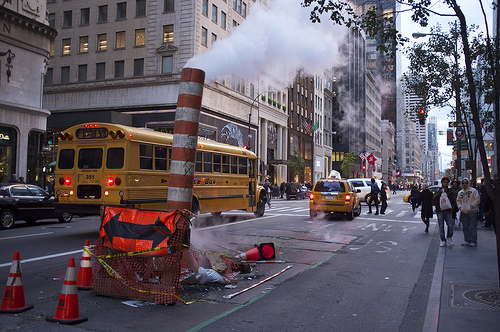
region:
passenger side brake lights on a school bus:
[105, 176, 115, 186]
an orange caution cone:
[47, 255, 89, 322]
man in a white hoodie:
[455, 177, 481, 245]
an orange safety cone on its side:
[232, 242, 276, 259]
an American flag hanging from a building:
[301, 116, 313, 133]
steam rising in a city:
[249, 8, 331, 69]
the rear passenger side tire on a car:
[1, 213, 13, 228]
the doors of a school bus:
[247, 155, 257, 210]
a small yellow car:
[309, 169, 361, 219]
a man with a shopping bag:
[436, 177, 454, 245]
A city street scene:
[8, 5, 498, 321]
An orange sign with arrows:
[86, 192, 182, 259]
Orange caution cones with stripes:
[1, 236, 99, 326]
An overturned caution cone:
[229, 235, 281, 265]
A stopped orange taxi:
[308, 169, 361, 218]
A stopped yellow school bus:
[56, 109, 284, 220]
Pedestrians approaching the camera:
[432, 177, 489, 322]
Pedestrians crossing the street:
[368, 167, 414, 220]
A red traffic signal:
[413, 106, 429, 126]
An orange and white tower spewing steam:
[163, 55, 210, 212]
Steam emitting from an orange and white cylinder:
[169, 2, 387, 121]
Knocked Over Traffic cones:
[203, 234, 306, 279]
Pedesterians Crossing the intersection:
[363, 174, 408, 231]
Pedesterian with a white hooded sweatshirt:
[454, 175, 486, 260]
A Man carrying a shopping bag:
[430, 175, 458, 254]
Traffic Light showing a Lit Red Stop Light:
[404, 101, 456, 128]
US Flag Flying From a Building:
[286, 116, 321, 141]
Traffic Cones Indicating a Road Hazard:
[3, 207, 310, 327]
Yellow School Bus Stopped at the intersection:
[47, 121, 326, 231]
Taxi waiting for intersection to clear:
[288, 167, 401, 227]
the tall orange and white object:
[165, 65, 205, 278]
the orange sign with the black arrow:
[98, 203, 178, 255]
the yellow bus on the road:
[53, 120, 267, 217]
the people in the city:
[0, 160, 499, 253]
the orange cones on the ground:
[1, 238, 276, 323]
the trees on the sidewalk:
[301, 0, 498, 292]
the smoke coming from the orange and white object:
[166, 0, 403, 284]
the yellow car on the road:
[308, 178, 360, 219]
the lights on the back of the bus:
[53, 121, 131, 206]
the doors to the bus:
[245, 155, 260, 212]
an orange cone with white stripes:
[46, 257, 95, 330]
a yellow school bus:
[49, 121, 271, 219]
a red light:
[415, 104, 429, 127]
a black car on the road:
[1, 179, 78, 228]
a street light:
[407, 19, 464, 180]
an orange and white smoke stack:
[156, 63, 209, 212]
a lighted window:
[92, 32, 112, 57]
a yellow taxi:
[307, 169, 365, 222]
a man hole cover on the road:
[455, 281, 498, 308]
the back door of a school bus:
[72, 142, 106, 203]